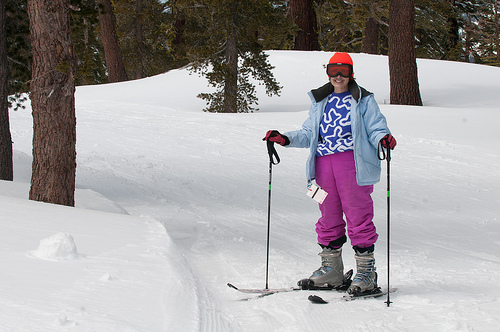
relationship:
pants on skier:
[310, 150, 387, 252] [250, 40, 412, 312]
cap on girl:
[329, 46, 355, 70] [258, 46, 400, 298]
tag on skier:
[303, 182, 327, 207] [277, 51, 401, 292]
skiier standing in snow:
[264, 48, 397, 296] [0, 43, 498, 327]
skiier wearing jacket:
[264, 48, 397, 296] [278, 83, 391, 191]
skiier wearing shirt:
[264, 48, 397, 296] [321, 96, 361, 158]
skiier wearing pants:
[264, 48, 397, 296] [313, 148, 380, 252]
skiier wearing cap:
[264, 48, 397, 296] [328, 52, 354, 78]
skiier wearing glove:
[264, 48, 397, 296] [265, 128, 289, 145]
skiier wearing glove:
[264, 48, 397, 296] [378, 131, 395, 147]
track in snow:
[211, 223, 291, 330] [0, 43, 498, 327]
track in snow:
[272, 248, 334, 330] [0, 43, 498, 327]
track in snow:
[87, 154, 211, 219] [0, 43, 498, 327]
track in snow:
[225, 171, 313, 202] [0, 43, 498, 327]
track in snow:
[235, 212, 315, 242] [0, 43, 498, 327]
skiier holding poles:
[262, 44, 396, 297] [263, 134, 275, 293]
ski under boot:
[225, 266, 353, 294] [297, 243, 345, 289]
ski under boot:
[306, 287, 400, 304] [346, 239, 378, 293]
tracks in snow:
[138, 180, 237, 325] [38, 201, 89, 273]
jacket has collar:
[279, 81, 386, 186] [304, 81, 362, 101]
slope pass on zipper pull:
[73, 101, 489, 262] [310, 186, 320, 198]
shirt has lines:
[312, 88, 354, 153] [319, 95, 344, 148]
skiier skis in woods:
[264, 48, 397, 296] [64, 15, 266, 115]